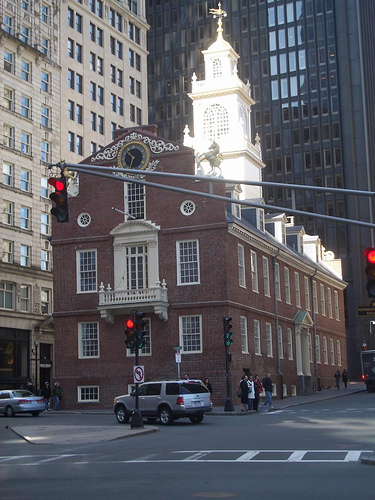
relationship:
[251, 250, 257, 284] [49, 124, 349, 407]
window on building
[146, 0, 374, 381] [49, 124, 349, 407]
building on building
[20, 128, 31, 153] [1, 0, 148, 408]
window on building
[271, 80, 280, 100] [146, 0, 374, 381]
window on building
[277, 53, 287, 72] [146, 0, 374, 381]
window on building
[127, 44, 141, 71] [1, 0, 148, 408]
window on building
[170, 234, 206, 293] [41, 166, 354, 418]
window on building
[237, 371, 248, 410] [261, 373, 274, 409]
person on person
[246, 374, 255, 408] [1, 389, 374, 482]
person on street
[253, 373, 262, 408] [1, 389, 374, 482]
person on street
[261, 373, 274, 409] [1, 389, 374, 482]
person on street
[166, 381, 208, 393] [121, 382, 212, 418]
window on car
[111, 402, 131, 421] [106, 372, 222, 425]
wheel on car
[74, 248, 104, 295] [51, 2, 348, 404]
window on building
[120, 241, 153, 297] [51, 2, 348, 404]
window on building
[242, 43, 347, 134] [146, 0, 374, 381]
window on building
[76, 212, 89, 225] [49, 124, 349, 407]
window on building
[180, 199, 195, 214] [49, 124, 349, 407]
window on building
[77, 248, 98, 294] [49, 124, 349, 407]
window on building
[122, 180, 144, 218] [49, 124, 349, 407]
window on building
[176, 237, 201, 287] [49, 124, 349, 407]
window on building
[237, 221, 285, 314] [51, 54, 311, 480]
window on building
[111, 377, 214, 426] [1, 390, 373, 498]
suv on street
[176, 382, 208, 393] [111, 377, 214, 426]
back window of suv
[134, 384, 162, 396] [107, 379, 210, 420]
window of suv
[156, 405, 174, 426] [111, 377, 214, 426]
tire of suv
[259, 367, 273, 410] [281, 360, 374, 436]
person crosses street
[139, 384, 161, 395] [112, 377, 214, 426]
window on suv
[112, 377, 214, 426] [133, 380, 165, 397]
suv has window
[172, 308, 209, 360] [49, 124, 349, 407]
window in building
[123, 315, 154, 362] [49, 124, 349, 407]
window in building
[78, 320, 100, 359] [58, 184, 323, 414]
window in building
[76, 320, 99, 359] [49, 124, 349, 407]
window in building